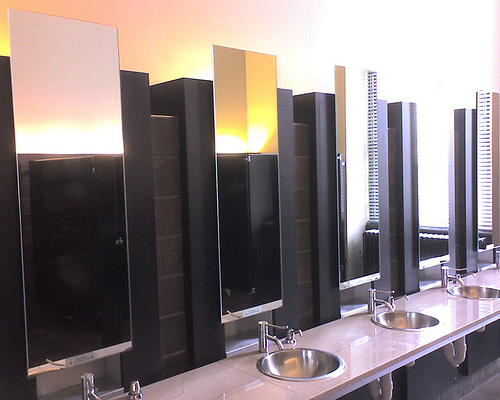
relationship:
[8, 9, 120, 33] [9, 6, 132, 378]
top of mirror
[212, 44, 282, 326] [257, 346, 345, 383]
mirror over sink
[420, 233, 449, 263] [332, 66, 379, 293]
radiator in mirror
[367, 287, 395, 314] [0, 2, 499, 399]
tap in scene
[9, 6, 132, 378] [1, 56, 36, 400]
mirror on wall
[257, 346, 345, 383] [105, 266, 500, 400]
sink in counter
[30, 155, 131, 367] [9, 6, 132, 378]
door in mirror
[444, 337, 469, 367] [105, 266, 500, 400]
pipe under counter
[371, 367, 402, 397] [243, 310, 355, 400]
pipe under sink